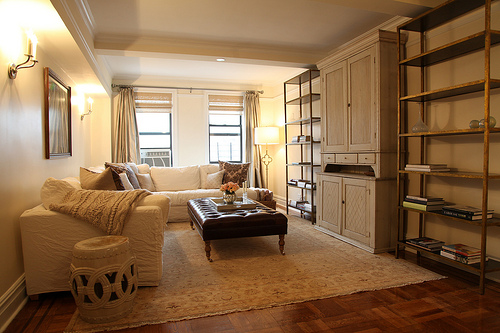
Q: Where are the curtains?
A: On the windows.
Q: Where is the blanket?
A: On the couch.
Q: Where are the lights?
A: On the wall.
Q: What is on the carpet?
A: The couch.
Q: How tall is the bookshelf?
A: Ceiling height.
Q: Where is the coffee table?
A: On the carpet.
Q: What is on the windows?
A: Tan curtains.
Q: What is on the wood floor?
A: Tan rug.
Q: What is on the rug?
A: The table and couch.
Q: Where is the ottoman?
A: Middle of the room.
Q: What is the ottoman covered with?
A: Leather.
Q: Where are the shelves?
A: Wall.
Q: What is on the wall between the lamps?
A: Painting.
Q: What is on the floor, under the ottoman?
A: Rug.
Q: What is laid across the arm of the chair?
A: Blanket.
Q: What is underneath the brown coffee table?
A: A rug.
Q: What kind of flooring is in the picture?
A: Wood.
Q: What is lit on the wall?
A: Electric wall sconces.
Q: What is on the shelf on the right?
A: Books.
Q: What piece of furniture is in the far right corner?
A: A lamp.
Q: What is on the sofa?
A: Pillows.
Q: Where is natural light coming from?
A: The two windows.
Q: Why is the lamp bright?
A: It is on.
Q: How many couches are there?
A: 1.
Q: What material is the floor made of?
A: Wood.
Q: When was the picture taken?
A: Daytime.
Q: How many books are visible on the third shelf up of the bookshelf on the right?
A: 2.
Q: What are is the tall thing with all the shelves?
A: Bookshelf.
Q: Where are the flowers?
A: On the tray.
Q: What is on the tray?
A: Flowers.